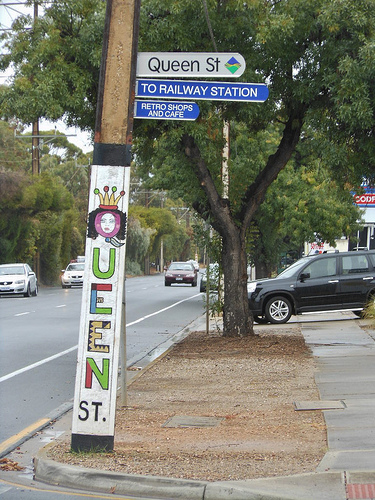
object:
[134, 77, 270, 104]
street sign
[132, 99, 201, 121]
street sign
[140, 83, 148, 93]
lettering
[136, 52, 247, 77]
sign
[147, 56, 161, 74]
lettering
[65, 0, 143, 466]
pole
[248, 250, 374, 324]
suv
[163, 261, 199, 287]
car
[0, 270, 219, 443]
road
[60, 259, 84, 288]
car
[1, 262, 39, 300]
car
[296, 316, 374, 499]
sidewalk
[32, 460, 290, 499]
gray curb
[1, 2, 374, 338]
tree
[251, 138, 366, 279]
tree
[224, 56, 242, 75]
diamond shape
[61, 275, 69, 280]
headlight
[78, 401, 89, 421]
words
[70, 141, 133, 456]
white sign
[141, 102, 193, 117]
"retro shops and .."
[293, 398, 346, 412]
square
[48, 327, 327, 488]
dirt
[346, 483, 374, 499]
brick pathway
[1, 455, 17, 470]
leaves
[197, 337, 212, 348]
gravel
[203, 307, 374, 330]
driveway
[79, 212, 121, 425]
queen st.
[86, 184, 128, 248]
queen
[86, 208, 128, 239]
hair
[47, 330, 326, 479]
gravel area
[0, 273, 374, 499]
sidewalk and street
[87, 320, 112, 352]
letter e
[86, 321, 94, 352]
stripes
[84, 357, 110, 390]
letter n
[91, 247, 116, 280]
letter u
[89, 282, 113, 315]
letter e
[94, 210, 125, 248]
letter q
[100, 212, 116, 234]
face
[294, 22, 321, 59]
leaves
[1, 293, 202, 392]
line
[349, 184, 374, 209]
sign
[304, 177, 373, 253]
building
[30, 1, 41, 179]
electrical pole